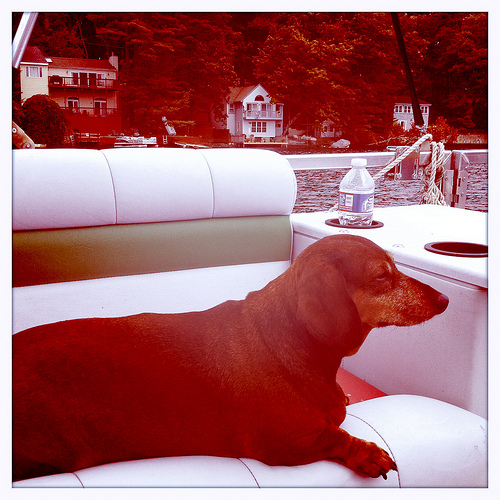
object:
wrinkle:
[243, 299, 300, 380]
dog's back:
[13, 280, 284, 383]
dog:
[13, 234, 449, 479]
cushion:
[11, 392, 484, 489]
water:
[336, 167, 374, 224]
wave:
[301, 172, 332, 203]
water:
[294, 161, 485, 211]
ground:
[274, 102, 485, 151]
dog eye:
[374, 268, 388, 282]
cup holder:
[423, 237, 488, 259]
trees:
[252, 26, 428, 141]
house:
[9, 40, 124, 134]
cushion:
[11, 214, 295, 287]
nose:
[432, 290, 448, 310]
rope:
[323, 134, 449, 212]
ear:
[298, 272, 365, 351]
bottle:
[336, 157, 377, 229]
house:
[226, 82, 285, 144]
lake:
[289, 146, 488, 213]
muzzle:
[374, 273, 449, 327]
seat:
[8, 144, 488, 489]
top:
[351, 157, 368, 168]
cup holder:
[324, 218, 383, 229]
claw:
[368, 447, 399, 481]